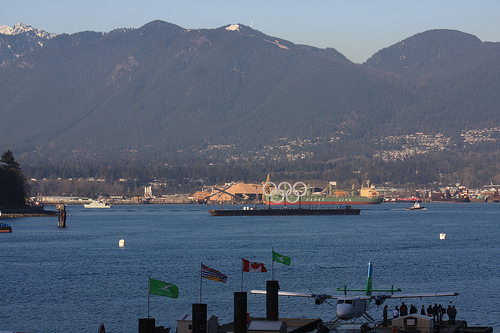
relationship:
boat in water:
[204, 193, 361, 218] [0, 202, 499, 331]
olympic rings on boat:
[258, 178, 310, 208] [209, 205, 362, 218]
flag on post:
[141, 267, 179, 302] [140, 319, 160, 329]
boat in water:
[187, 174, 387, 234] [232, 220, 392, 252]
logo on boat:
[261, 181, 308, 204] [207, 179, 357, 215]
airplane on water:
[249, 261, 461, 323] [0, 202, 499, 331]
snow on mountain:
[221, 25, 240, 30] [8, 22, 390, 135]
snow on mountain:
[6, 25, 38, 32] [8, 22, 390, 135]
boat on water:
[204, 193, 361, 218] [371, 220, 445, 262]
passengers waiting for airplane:
[446, 296, 459, 323] [249, 261, 461, 323]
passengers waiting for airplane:
[382, 302, 389, 326] [249, 261, 461, 323]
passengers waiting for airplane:
[392, 305, 399, 321] [249, 261, 461, 323]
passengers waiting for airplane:
[399, 299, 409, 319] [249, 261, 461, 323]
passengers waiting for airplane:
[411, 302, 416, 317] [249, 261, 461, 323]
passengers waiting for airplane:
[418, 305, 426, 314] [249, 261, 461, 323]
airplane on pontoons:
[249, 257, 463, 329] [250, 258, 460, 331]